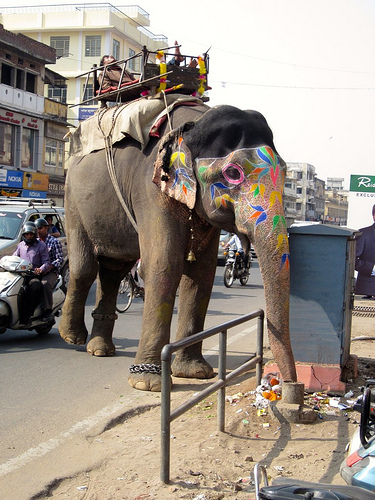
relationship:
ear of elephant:
[147, 143, 203, 201] [58, 102, 296, 389]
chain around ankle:
[128, 363, 172, 374] [109, 332, 211, 379]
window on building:
[47, 36, 74, 63] [31, 0, 141, 145]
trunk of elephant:
[243, 185, 297, 385] [58, 102, 296, 389]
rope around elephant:
[93, 99, 141, 240] [43, 90, 307, 418]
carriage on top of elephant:
[69, 40, 212, 108] [58, 102, 296, 389]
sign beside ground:
[349, 174, 373, 193] [0, 291, 375, 496]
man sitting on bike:
[12, 220, 51, 304] [0, 255, 67, 339]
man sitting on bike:
[36, 217, 62, 278] [0, 255, 67, 339]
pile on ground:
[215, 369, 367, 436] [0, 248, 373, 497]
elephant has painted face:
[58, 102, 296, 389] [211, 147, 294, 267]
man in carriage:
[98, 41, 198, 90] [69, 40, 212, 108]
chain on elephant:
[128, 363, 172, 374] [58, 102, 296, 389]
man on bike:
[12, 220, 42, 327] [0, 255, 70, 339]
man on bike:
[34, 218, 64, 323] [0, 255, 70, 339]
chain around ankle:
[128, 363, 172, 374] [129, 356, 165, 374]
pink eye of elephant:
[219, 161, 244, 184] [45, 92, 317, 396]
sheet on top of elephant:
[100, 106, 141, 146] [58, 102, 296, 389]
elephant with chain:
[58, 102, 296, 389] [129, 363, 161, 373]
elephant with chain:
[58, 102, 296, 389] [91, 308, 118, 320]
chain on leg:
[129, 363, 161, 373] [128, 191, 191, 391]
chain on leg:
[91, 308, 118, 320] [86, 257, 138, 357]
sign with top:
[346, 174, 374, 296] [350, 171, 371, 207]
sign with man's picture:
[346, 174, 374, 296] [353, 200, 372, 294]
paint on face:
[151, 123, 304, 254] [218, 125, 293, 236]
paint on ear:
[151, 123, 304, 254] [149, 131, 199, 213]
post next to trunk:
[284, 214, 363, 394] [247, 218, 300, 385]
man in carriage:
[85, 41, 152, 106] [73, 39, 212, 107]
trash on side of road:
[183, 373, 373, 497] [5, 280, 373, 497]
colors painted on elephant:
[158, 132, 295, 271] [58, 118, 314, 439]